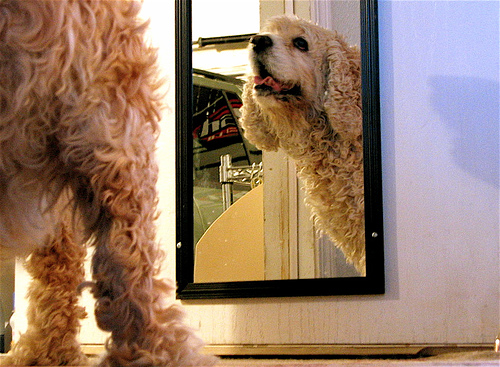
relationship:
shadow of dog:
[421, 56, 496, 209] [4, 9, 148, 316]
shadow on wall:
[421, 56, 496, 209] [409, 12, 453, 46]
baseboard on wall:
[278, 338, 480, 364] [409, 12, 453, 46]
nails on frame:
[362, 227, 388, 255] [355, 7, 387, 106]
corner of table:
[245, 182, 260, 199] [203, 200, 269, 287]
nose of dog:
[254, 38, 276, 55] [4, 9, 148, 316]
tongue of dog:
[253, 71, 301, 95] [4, 9, 148, 316]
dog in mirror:
[4, 9, 148, 316] [150, 6, 406, 304]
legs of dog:
[22, 239, 185, 363] [4, 9, 148, 316]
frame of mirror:
[355, 7, 387, 106] [150, 6, 406, 304]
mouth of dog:
[249, 53, 302, 100] [4, 9, 148, 316]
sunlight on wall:
[146, 16, 184, 96] [409, 12, 453, 46]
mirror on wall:
[150, 6, 406, 304] [409, 12, 453, 46]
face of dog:
[244, 20, 343, 146] [4, 9, 148, 316]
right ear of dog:
[242, 75, 261, 163] [4, 9, 148, 316]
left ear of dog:
[325, 34, 356, 145] [4, 9, 148, 316]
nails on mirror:
[362, 227, 388, 255] [150, 6, 406, 304]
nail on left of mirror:
[163, 227, 190, 268] [150, 6, 406, 304]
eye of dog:
[290, 29, 312, 57] [4, 9, 148, 316]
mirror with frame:
[150, 6, 406, 304] [355, 7, 387, 106]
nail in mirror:
[163, 227, 190, 268] [150, 6, 406, 304]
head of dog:
[244, 20, 343, 146] [4, 9, 148, 316]